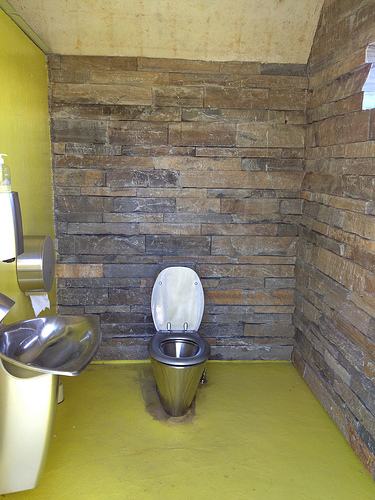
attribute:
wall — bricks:
[46, 54, 307, 360]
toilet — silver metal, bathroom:
[150, 329, 214, 409]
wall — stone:
[51, 58, 297, 340]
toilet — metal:
[145, 267, 207, 417]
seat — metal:
[153, 327, 208, 366]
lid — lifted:
[147, 264, 205, 331]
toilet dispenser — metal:
[21, 234, 53, 308]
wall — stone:
[304, 3, 373, 422]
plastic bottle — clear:
[1, 155, 8, 184]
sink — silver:
[2, 317, 96, 370]